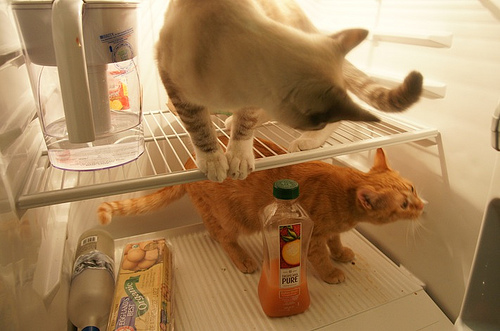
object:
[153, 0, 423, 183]
cat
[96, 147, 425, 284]
cat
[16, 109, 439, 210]
wire shelf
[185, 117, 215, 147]
stripes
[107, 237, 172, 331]
carton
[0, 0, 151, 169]
pitcher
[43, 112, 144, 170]
water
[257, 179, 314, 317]
bottle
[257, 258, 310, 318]
orange juice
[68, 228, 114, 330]
bottle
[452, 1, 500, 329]
door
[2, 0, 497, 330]
kitchen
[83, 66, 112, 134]
filter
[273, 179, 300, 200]
lid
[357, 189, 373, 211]
ear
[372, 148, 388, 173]
ear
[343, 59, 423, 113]
tail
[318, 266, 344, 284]
paw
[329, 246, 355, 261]
paw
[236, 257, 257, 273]
paw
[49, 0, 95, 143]
handle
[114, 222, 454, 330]
shelf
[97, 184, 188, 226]
tail